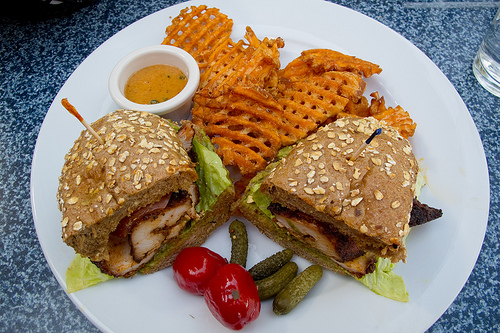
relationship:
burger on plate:
[282, 122, 398, 285] [30, 0, 490, 333]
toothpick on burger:
[50, 94, 109, 142] [282, 122, 398, 285]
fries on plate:
[211, 43, 295, 121] [30, 0, 490, 333]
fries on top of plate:
[211, 43, 295, 121] [30, 0, 490, 333]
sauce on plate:
[111, 53, 217, 126] [30, 0, 490, 333]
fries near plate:
[211, 43, 295, 121] [30, 0, 490, 333]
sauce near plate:
[111, 53, 217, 126] [30, 0, 490, 333]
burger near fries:
[282, 122, 398, 285] [211, 43, 295, 121]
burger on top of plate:
[282, 122, 398, 285] [30, 0, 490, 333]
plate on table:
[30, 0, 490, 333] [14, 26, 51, 59]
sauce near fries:
[111, 53, 217, 126] [211, 43, 295, 121]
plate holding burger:
[30, 0, 490, 333] [282, 122, 398, 285]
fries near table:
[211, 43, 295, 121] [14, 26, 51, 59]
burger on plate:
[282, 122, 398, 285] [417, 94, 480, 205]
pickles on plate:
[224, 221, 298, 274] [398, 69, 469, 174]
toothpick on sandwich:
[366, 118, 386, 158] [249, 87, 429, 271]